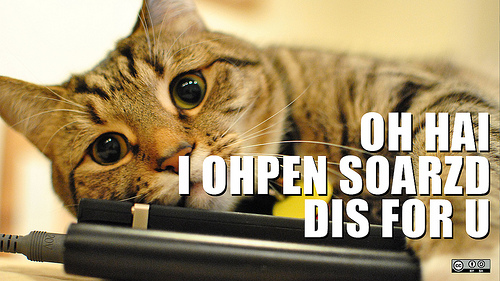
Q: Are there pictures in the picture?
A: No, there are no pictures.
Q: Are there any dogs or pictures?
A: No, there are no pictures or dogs.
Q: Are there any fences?
A: No, there are no fences.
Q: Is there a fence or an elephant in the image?
A: No, there are no fences or elephants.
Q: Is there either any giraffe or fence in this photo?
A: No, there are no fences or giraffes.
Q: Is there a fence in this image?
A: No, there are no fences.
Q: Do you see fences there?
A: No, there are no fences.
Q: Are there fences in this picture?
A: No, there are no fences.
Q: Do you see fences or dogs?
A: No, there are no fences or dogs.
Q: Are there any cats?
A: Yes, there is a cat.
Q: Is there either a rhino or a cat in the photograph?
A: Yes, there is a cat.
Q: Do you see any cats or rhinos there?
A: Yes, there is a cat.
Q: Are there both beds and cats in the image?
A: No, there is a cat but no beds.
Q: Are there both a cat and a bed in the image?
A: No, there is a cat but no beds.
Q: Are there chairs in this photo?
A: No, there are no chairs.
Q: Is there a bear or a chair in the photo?
A: No, there are no chairs or bears.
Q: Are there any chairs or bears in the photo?
A: No, there are no chairs or bears.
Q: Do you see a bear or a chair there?
A: No, there are no chairs or bears.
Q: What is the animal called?
A: The animal is a cat.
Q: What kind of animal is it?
A: The animal is a cat.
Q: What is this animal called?
A: This is a cat.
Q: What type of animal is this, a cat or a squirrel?
A: This is a cat.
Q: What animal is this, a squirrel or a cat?
A: This is a cat.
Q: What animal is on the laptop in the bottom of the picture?
A: The cat is on the laptop.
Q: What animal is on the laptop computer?
A: The animal is a cat.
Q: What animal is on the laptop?
A: The animal is a cat.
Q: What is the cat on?
A: The cat is on the laptop computer.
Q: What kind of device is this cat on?
A: The cat is on the laptop.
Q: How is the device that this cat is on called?
A: The device is a laptop.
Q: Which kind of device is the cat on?
A: The cat is on the laptop.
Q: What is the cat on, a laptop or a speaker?
A: The cat is on a laptop.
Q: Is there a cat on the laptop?
A: Yes, there is a cat on the laptop.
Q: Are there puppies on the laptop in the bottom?
A: No, there is a cat on the laptop computer.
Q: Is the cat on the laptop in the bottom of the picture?
A: Yes, the cat is on the laptop.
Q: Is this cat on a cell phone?
A: No, the cat is on the laptop.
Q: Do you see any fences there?
A: No, there are no fences.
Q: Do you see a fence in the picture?
A: No, there are no fences.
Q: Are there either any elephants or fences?
A: No, there are no fences or elephants.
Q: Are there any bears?
A: No, there are no bears.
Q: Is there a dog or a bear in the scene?
A: No, there are no bears or dogs.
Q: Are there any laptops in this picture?
A: Yes, there is a laptop.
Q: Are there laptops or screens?
A: Yes, there is a laptop.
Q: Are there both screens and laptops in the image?
A: No, there is a laptop but no screens.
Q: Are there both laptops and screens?
A: No, there is a laptop but no screens.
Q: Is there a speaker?
A: No, there are no speakers.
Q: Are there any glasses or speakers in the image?
A: No, there are no speakers or glasses.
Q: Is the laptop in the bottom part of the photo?
A: Yes, the laptop is in the bottom of the image.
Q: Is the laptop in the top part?
A: No, the laptop is in the bottom of the image.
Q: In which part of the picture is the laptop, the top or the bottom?
A: The laptop is in the bottom of the image.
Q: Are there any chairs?
A: No, there are no chairs.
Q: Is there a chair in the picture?
A: No, there are no chairs.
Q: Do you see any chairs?
A: No, there are no chairs.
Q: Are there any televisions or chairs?
A: No, there are no chairs or televisions.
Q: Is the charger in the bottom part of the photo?
A: Yes, the charger is in the bottom of the image.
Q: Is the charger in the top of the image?
A: No, the charger is in the bottom of the image.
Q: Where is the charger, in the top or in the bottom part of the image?
A: The charger is in the bottom of the image.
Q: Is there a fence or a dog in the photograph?
A: No, there are no fences or dogs.